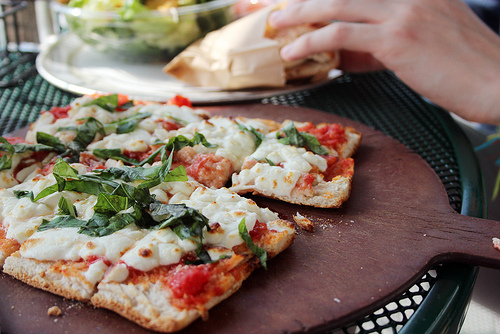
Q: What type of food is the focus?
A: Pizza.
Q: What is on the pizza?
A: Cheese and basil.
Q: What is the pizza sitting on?
A: A paddle.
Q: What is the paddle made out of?
A: Wood.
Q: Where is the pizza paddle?
A: The table.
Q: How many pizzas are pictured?
A: One.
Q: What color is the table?
A: Black.